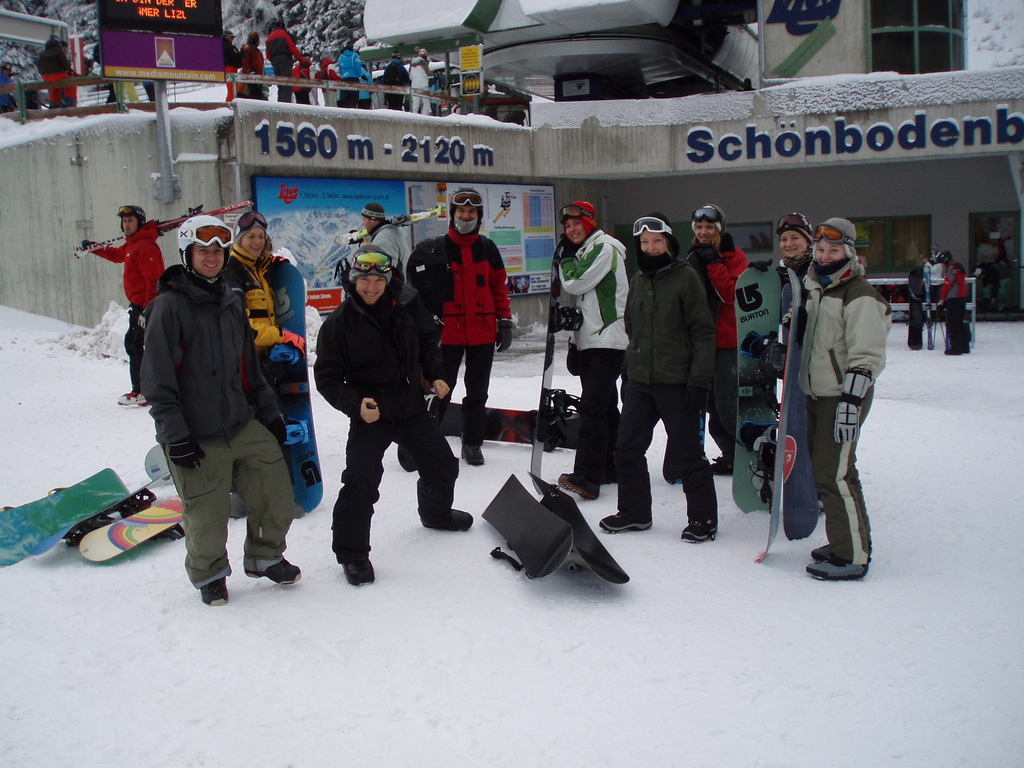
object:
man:
[142, 216, 297, 603]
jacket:
[139, 273, 286, 447]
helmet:
[175, 212, 240, 281]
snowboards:
[479, 474, 574, 589]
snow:
[506, 580, 690, 658]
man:
[316, 247, 474, 581]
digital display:
[98, 30, 236, 83]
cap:
[559, 201, 598, 245]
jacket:
[548, 227, 633, 350]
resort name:
[683, 104, 1021, 166]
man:
[80, 204, 172, 407]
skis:
[82, 188, 267, 253]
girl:
[603, 207, 720, 541]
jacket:
[619, 260, 719, 387]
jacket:
[88, 217, 166, 307]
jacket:
[314, 286, 448, 424]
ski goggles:
[183, 222, 242, 249]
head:
[173, 215, 234, 284]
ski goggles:
[343, 250, 401, 280]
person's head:
[343, 250, 401, 309]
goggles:
[632, 217, 674, 237]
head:
[630, 210, 678, 272]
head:
[693, 204, 726, 247]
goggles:
[688, 206, 721, 223]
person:
[681, 203, 752, 475]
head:
[811, 219, 854, 267]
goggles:
[812, 221, 853, 244]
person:
[788, 216, 901, 580]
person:
[224, 209, 301, 484]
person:
[411, 186, 517, 471]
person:
[540, 202, 638, 506]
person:
[599, 213, 722, 539]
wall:
[95, 1, 227, 81]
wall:
[235, 91, 985, 167]